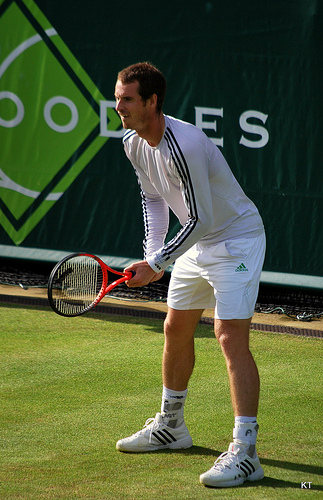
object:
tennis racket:
[47, 251, 136, 319]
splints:
[232, 420, 259, 445]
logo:
[1, 0, 123, 247]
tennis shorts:
[166, 232, 266, 320]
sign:
[0, 0, 270, 247]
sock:
[162, 386, 188, 413]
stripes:
[244, 458, 256, 473]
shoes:
[115, 412, 193, 451]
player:
[114, 63, 267, 490]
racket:
[47, 251, 137, 318]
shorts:
[166, 232, 267, 320]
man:
[113, 60, 267, 490]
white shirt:
[122, 113, 265, 271]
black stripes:
[161, 126, 198, 262]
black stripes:
[121, 128, 148, 260]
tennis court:
[0, 292, 322, 500]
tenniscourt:
[0, 303, 319, 497]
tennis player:
[113, 60, 265, 487]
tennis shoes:
[115, 412, 193, 452]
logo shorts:
[167, 237, 269, 320]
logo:
[235, 262, 249, 273]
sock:
[232, 415, 257, 443]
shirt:
[123, 114, 265, 268]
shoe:
[198, 441, 265, 488]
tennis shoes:
[199, 439, 264, 488]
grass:
[0, 297, 323, 499]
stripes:
[160, 126, 198, 261]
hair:
[118, 61, 167, 116]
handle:
[123, 269, 136, 280]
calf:
[245, 352, 262, 417]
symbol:
[234, 260, 250, 274]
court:
[0, 293, 323, 499]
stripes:
[121, 129, 148, 262]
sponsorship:
[0, 0, 272, 249]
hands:
[124, 260, 156, 288]